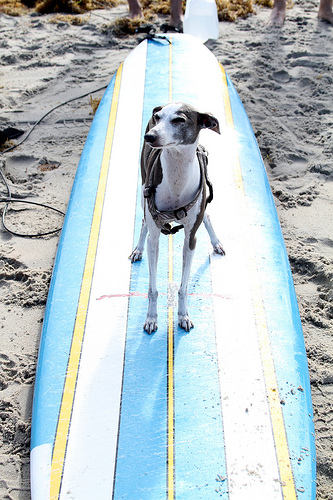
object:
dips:
[267, 154, 312, 198]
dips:
[0, 270, 46, 308]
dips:
[0, 350, 38, 390]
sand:
[59, 194, 68, 209]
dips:
[290, 249, 332, 332]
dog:
[125, 97, 226, 342]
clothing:
[139, 120, 217, 250]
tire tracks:
[3, 113, 93, 131]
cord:
[0, 82, 110, 242]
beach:
[0, 0, 333, 500]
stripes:
[59, 39, 147, 500]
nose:
[143, 129, 158, 144]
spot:
[186, 110, 189, 113]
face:
[144, 102, 199, 151]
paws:
[177, 313, 194, 333]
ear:
[197, 110, 222, 140]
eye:
[171, 116, 186, 123]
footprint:
[310, 382, 333, 450]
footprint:
[286, 257, 333, 334]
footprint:
[268, 66, 291, 86]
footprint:
[0, 345, 39, 384]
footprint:
[0, 252, 50, 303]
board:
[24, 28, 321, 497]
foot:
[265, 5, 289, 31]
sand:
[287, 216, 295, 229]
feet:
[160, 11, 185, 35]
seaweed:
[31, 1, 112, 17]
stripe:
[165, 33, 177, 495]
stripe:
[173, 233, 229, 500]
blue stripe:
[228, 70, 316, 498]